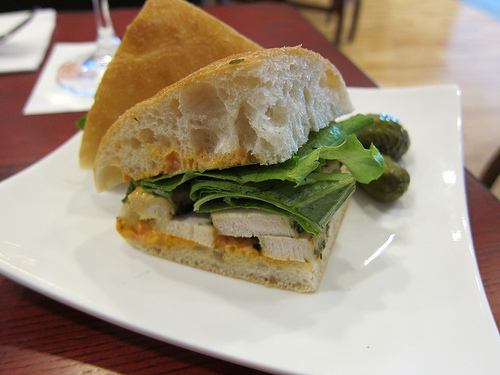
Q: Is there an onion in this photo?
A: No, there are no onions.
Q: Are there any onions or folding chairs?
A: No, there are no onions or folding chairs.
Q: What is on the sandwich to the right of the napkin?
A: The chicken is on the sandwich.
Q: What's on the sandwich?
A: The chicken is on the sandwich.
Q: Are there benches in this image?
A: No, there are no benches.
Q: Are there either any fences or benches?
A: No, there are no benches or fences.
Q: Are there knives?
A: No, there are no knives.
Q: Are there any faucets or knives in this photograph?
A: No, there are no knives or faucets.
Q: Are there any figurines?
A: No, there are no figurines.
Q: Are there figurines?
A: No, there are no figurines.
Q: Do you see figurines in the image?
A: No, there are no figurines.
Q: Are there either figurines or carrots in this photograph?
A: No, there are no figurines or carrots.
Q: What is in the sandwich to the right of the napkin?
A: The chicken is in the sandwich.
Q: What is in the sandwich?
A: The chicken is in the sandwich.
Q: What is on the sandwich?
A: The chicken is on the sandwich.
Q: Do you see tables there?
A: Yes, there is a table.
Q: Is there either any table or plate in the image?
A: Yes, there is a table.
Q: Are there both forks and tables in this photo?
A: No, there is a table but no forks.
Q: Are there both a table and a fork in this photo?
A: No, there is a table but no forks.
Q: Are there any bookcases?
A: No, there are no bookcases.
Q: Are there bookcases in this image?
A: No, there are no bookcases.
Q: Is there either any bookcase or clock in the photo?
A: No, there are no bookcases or clocks.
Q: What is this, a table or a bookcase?
A: This is a table.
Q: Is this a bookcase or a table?
A: This is a table.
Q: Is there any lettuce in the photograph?
A: Yes, there is lettuce.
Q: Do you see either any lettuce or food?
A: Yes, there is lettuce.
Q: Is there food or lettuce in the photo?
A: Yes, there is lettuce.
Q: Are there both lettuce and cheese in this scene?
A: No, there is lettuce but no cheese.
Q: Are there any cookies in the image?
A: No, there are no cookies.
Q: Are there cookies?
A: No, there are no cookies.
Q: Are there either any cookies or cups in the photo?
A: No, there are no cookies or cups.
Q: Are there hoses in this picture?
A: No, there are no hoses.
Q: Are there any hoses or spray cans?
A: No, there are no hoses or spray cans.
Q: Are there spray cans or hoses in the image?
A: No, there are no hoses or spray cans.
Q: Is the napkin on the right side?
A: No, the napkin is on the left of the image.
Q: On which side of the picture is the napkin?
A: The napkin is on the left of the image.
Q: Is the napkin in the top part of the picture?
A: Yes, the napkin is in the top of the image.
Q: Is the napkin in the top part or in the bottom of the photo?
A: The napkin is in the top of the image.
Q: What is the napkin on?
A: The napkin is on the table.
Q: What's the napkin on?
A: The napkin is on the table.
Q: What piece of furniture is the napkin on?
A: The napkin is on the table.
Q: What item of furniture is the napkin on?
A: The napkin is on the table.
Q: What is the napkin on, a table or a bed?
A: The napkin is on a table.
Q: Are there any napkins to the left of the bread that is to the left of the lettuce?
A: Yes, there is a napkin to the left of the bread.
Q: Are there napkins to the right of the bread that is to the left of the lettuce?
A: No, the napkin is to the left of the bread.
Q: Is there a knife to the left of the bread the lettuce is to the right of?
A: No, there is a napkin to the left of the bread.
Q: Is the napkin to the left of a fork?
A: No, the napkin is to the left of the bread.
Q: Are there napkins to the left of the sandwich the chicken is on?
A: Yes, there is a napkin to the left of the sandwich.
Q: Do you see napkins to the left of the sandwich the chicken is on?
A: Yes, there is a napkin to the left of the sandwich.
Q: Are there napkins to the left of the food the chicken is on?
A: Yes, there is a napkin to the left of the sandwich.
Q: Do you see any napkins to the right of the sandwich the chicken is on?
A: No, the napkin is to the left of the sandwich.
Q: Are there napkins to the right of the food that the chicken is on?
A: No, the napkin is to the left of the sandwich.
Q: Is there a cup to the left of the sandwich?
A: No, there is a napkin to the left of the sandwich.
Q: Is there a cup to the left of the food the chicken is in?
A: No, there is a napkin to the left of the sandwich.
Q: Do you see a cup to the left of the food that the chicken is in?
A: No, there is a napkin to the left of the sandwich.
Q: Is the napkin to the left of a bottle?
A: No, the napkin is to the left of the sandwich.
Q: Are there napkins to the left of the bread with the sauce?
A: Yes, there is a napkin to the left of the bread.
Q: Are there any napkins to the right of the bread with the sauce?
A: No, the napkin is to the left of the bread.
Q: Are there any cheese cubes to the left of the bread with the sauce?
A: No, there is a napkin to the left of the bread.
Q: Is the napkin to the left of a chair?
A: No, the napkin is to the left of a bread.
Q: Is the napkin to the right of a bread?
A: No, the napkin is to the left of a bread.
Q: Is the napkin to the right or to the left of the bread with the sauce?
A: The napkin is to the left of the bread.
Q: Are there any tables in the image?
A: Yes, there is a table.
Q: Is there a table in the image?
A: Yes, there is a table.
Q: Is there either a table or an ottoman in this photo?
A: Yes, there is a table.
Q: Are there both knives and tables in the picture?
A: No, there is a table but no knives.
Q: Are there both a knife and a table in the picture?
A: No, there is a table but no knives.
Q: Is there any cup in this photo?
A: No, there are no cups.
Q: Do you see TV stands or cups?
A: No, there are no cups or TV stands.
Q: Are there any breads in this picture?
A: Yes, there is a bread.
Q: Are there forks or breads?
A: Yes, there is a bread.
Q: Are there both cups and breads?
A: No, there is a bread but no cups.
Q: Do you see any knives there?
A: No, there are no knives.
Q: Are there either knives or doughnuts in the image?
A: No, there are no knives or doughnuts.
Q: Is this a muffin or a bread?
A: This is a bread.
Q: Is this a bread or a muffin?
A: This is a bread.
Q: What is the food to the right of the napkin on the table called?
A: The food is a bread.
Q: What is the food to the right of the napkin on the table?
A: The food is a bread.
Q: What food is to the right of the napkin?
A: The food is a bread.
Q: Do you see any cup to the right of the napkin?
A: No, there is a bread to the right of the napkin.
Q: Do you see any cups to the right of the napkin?
A: No, there is a bread to the right of the napkin.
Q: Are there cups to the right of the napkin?
A: No, there is a bread to the right of the napkin.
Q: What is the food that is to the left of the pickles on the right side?
A: The food is a bread.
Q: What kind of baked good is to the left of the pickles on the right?
A: The food is a bread.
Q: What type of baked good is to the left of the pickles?
A: The food is a bread.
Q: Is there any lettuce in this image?
A: Yes, there is lettuce.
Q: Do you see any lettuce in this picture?
A: Yes, there is lettuce.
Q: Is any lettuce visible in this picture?
A: Yes, there is lettuce.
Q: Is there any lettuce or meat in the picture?
A: Yes, there is lettuce.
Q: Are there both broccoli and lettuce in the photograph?
A: No, there is lettuce but no broccoli.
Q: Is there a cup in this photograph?
A: No, there are no cups.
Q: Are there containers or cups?
A: No, there are no cups or containers.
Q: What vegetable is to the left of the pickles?
A: The vegetable is lettuce.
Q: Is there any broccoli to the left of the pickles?
A: No, there is lettuce to the left of the pickles.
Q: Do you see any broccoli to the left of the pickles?
A: No, there is lettuce to the left of the pickles.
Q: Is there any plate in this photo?
A: Yes, there is a plate.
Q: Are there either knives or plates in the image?
A: Yes, there is a plate.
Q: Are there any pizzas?
A: No, there are no pizzas.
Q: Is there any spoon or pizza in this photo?
A: No, there are no pizzas or spoons.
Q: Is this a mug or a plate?
A: This is a plate.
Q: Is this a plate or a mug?
A: This is a plate.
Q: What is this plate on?
A: The plate is on the table.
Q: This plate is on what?
A: The plate is on the table.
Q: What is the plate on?
A: The plate is on the table.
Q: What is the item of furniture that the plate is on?
A: The piece of furniture is a table.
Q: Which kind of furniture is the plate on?
A: The plate is on the table.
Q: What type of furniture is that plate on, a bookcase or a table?
A: The plate is on a table.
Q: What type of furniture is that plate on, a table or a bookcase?
A: The plate is on a table.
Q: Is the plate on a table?
A: Yes, the plate is on a table.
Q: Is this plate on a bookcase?
A: No, the plate is on a table.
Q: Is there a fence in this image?
A: No, there are no fences.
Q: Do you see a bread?
A: Yes, there is a bread.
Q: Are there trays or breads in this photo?
A: Yes, there is a bread.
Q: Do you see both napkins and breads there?
A: Yes, there are both a bread and a napkin.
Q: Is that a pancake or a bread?
A: That is a bread.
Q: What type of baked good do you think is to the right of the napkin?
A: The food is a bread.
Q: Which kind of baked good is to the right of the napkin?
A: The food is a bread.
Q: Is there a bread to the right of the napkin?
A: Yes, there is a bread to the right of the napkin.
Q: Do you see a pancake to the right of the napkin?
A: No, there is a bread to the right of the napkin.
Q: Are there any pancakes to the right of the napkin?
A: No, there is a bread to the right of the napkin.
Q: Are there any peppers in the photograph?
A: No, there are no peppers.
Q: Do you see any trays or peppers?
A: No, there are no peppers or trays.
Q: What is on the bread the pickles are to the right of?
A: The sauce is on the bread.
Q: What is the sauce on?
A: The sauce is on the bread.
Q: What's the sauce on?
A: The sauce is on the bread.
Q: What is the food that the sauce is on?
A: The food is a bread.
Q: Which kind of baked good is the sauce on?
A: The sauce is on the bread.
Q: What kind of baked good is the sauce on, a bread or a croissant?
A: The sauce is on a bread.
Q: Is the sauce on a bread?
A: Yes, the sauce is on a bread.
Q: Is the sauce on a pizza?
A: No, the sauce is on a bread.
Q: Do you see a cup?
A: No, there are no cups.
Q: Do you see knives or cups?
A: No, there are no cups or knives.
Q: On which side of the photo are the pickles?
A: The pickles are on the right of the image.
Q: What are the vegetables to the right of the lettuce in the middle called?
A: The vegetables are pickles.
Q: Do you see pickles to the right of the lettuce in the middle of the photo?
A: Yes, there are pickles to the right of the lettuce.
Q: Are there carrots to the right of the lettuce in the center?
A: No, there are pickles to the right of the lettuce.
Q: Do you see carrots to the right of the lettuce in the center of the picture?
A: No, there are pickles to the right of the lettuce.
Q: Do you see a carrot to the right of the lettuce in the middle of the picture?
A: No, there are pickles to the right of the lettuce.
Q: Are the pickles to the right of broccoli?
A: No, the pickles are to the right of the lettuce.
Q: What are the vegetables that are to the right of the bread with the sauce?
A: The vegetables are pickles.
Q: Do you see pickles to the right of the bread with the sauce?
A: Yes, there are pickles to the right of the bread.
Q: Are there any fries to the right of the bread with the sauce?
A: No, there are pickles to the right of the bread.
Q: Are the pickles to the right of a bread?
A: Yes, the pickles are to the right of a bread.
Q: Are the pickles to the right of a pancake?
A: No, the pickles are to the right of a bread.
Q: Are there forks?
A: No, there are no forks.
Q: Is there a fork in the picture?
A: No, there are no forks.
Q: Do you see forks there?
A: No, there are no forks.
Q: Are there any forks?
A: No, there are no forks.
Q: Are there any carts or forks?
A: No, there are no forks or carts.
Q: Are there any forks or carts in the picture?
A: No, there are no forks or carts.